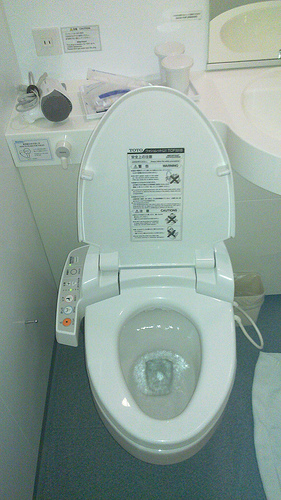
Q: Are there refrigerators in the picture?
A: No, there are no refrigerators.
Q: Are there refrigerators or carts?
A: No, there are no refrigerators or carts.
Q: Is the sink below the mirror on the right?
A: Yes, the sink is below the mirror.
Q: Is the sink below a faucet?
A: No, the sink is below the mirror.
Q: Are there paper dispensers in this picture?
A: No, there are no paper dispensers.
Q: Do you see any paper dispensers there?
A: No, there are no paper dispensers.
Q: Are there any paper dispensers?
A: No, there are no paper dispensers.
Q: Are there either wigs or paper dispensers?
A: No, there are no paper dispensers or wigs.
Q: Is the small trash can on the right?
A: Yes, the garbage can is on the right of the image.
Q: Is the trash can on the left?
A: No, the trash can is on the right of the image.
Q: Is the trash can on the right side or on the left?
A: The trash can is on the right of the image.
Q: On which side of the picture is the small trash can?
A: The trash bin is on the right of the image.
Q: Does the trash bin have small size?
A: Yes, the trash bin is small.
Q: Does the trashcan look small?
A: Yes, the trashcan is small.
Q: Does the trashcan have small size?
A: Yes, the trashcan is small.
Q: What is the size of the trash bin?
A: The trash bin is small.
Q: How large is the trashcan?
A: The trashcan is small.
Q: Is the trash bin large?
A: No, the trash bin is small.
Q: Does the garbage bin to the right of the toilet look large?
A: No, the trash can is small.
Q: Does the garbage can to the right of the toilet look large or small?
A: The trash can is small.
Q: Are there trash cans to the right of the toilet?
A: Yes, there is a trash can to the right of the toilet.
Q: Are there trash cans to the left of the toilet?
A: No, the trash can is to the right of the toilet.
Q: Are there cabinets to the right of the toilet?
A: No, there is a trash can to the right of the toilet.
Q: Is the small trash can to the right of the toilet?
A: Yes, the garbage bin is to the right of the toilet.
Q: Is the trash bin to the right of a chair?
A: No, the trash bin is to the right of the toilet.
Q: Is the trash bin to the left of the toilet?
A: No, the trash bin is to the right of the toilet.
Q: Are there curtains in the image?
A: No, there are no curtains.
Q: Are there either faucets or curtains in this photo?
A: No, there are no curtains or faucets.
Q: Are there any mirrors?
A: Yes, there is a mirror.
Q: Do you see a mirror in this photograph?
A: Yes, there is a mirror.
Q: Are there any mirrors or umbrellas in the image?
A: Yes, there is a mirror.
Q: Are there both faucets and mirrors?
A: No, there is a mirror but no faucets.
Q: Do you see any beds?
A: No, there are no beds.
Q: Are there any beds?
A: No, there are no beds.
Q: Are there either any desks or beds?
A: No, there are no beds or desks.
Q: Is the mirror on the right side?
A: Yes, the mirror is on the right of the image.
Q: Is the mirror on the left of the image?
A: No, the mirror is on the right of the image.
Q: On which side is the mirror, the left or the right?
A: The mirror is on the right of the image.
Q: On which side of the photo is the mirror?
A: The mirror is on the right of the image.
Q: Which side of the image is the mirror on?
A: The mirror is on the right of the image.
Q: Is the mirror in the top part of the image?
A: Yes, the mirror is in the top of the image.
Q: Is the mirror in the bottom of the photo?
A: No, the mirror is in the top of the image.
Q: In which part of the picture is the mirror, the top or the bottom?
A: The mirror is in the top of the image.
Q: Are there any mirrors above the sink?
A: Yes, there is a mirror above the sink.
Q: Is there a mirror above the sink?
A: Yes, there is a mirror above the sink.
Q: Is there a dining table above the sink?
A: No, there is a mirror above the sink.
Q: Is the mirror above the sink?
A: Yes, the mirror is above the sink.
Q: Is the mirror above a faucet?
A: No, the mirror is above the sink.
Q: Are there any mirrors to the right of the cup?
A: Yes, there is a mirror to the right of the cup.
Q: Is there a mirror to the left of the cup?
A: No, the mirror is to the right of the cup.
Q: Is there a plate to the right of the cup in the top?
A: No, there is a mirror to the right of the cup.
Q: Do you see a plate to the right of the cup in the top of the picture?
A: No, there is a mirror to the right of the cup.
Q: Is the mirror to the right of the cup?
A: Yes, the mirror is to the right of the cup.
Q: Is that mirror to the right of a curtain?
A: No, the mirror is to the right of the cup.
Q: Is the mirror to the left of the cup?
A: No, the mirror is to the right of the cup.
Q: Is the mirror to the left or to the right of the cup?
A: The mirror is to the right of the cup.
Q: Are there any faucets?
A: No, there are no faucets.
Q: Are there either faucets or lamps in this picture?
A: No, there are no faucets or lamps.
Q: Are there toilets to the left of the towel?
A: Yes, there is a toilet to the left of the towel.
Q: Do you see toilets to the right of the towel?
A: No, the toilet is to the left of the towel.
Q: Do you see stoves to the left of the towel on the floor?
A: No, there is a toilet to the left of the towel.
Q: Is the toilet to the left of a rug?
A: No, the toilet is to the left of the towel.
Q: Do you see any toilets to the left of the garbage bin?
A: Yes, there is a toilet to the left of the garbage bin.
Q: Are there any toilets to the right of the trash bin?
A: No, the toilet is to the left of the trash bin.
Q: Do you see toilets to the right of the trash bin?
A: No, the toilet is to the left of the trash bin.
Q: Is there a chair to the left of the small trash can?
A: No, there is a toilet to the left of the garbage bin.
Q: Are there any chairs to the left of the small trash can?
A: No, there is a toilet to the left of the garbage bin.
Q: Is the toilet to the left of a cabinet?
A: No, the toilet is to the left of the garbage bin.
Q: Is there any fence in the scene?
A: No, there are no fences.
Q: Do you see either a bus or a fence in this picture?
A: No, there are no fences or buses.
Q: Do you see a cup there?
A: Yes, there is a cup.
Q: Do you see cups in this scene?
A: Yes, there is a cup.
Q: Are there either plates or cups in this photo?
A: Yes, there is a cup.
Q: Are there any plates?
A: No, there are no plates.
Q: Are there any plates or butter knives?
A: No, there are no plates or butter knives.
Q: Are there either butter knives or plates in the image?
A: No, there are no plates or butter knives.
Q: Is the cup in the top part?
A: Yes, the cup is in the top of the image.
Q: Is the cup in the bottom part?
A: No, the cup is in the top of the image.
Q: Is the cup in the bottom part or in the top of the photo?
A: The cup is in the top of the image.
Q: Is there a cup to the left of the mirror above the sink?
A: Yes, there is a cup to the left of the mirror.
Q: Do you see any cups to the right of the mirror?
A: No, the cup is to the left of the mirror.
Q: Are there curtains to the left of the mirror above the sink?
A: No, there is a cup to the left of the mirror.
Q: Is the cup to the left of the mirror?
A: Yes, the cup is to the left of the mirror.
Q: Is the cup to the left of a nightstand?
A: No, the cup is to the left of the mirror.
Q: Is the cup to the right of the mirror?
A: No, the cup is to the left of the mirror.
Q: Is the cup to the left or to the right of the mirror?
A: The cup is to the left of the mirror.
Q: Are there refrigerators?
A: No, there are no refrigerators.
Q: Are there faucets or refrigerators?
A: No, there are no refrigerators or faucets.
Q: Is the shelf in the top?
A: Yes, the shelf is in the top of the image.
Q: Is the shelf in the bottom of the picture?
A: No, the shelf is in the top of the image.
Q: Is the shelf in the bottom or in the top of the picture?
A: The shelf is in the top of the image.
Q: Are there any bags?
A: No, there are no bags.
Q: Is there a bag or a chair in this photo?
A: No, there are no bags or chairs.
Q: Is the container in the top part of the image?
A: Yes, the container is in the top of the image.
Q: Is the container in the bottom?
A: No, the container is in the top of the image.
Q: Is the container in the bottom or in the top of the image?
A: The container is in the top of the image.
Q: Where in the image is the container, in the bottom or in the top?
A: The container is in the top of the image.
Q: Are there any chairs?
A: No, there are no chairs.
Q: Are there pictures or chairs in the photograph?
A: No, there are no chairs or pictures.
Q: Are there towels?
A: Yes, there is a towel.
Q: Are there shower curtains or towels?
A: Yes, there is a towel.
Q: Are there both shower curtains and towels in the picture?
A: No, there is a towel but no shower curtains.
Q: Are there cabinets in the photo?
A: No, there are no cabinets.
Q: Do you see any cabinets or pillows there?
A: No, there are no cabinets or pillows.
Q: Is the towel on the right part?
A: Yes, the towel is on the right of the image.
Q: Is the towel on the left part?
A: No, the towel is on the right of the image.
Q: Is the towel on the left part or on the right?
A: The towel is on the right of the image.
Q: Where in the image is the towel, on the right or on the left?
A: The towel is on the right of the image.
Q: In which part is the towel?
A: The towel is on the right of the image.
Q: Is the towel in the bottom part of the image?
A: Yes, the towel is in the bottom of the image.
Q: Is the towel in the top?
A: No, the towel is in the bottom of the image.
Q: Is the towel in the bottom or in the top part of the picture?
A: The towel is in the bottom of the image.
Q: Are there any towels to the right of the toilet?
A: Yes, there is a towel to the right of the toilet.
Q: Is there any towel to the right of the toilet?
A: Yes, there is a towel to the right of the toilet.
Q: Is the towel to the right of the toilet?
A: Yes, the towel is to the right of the toilet.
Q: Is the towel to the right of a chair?
A: No, the towel is to the right of the toilet.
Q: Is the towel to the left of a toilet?
A: No, the towel is to the right of a toilet.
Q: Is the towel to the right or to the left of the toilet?
A: The towel is to the right of the toilet.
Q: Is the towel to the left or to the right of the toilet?
A: The towel is to the right of the toilet.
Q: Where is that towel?
A: The towel is on the floor.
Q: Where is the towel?
A: The towel is on the floor.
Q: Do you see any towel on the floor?
A: Yes, there is a towel on the floor.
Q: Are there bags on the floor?
A: No, there is a towel on the floor.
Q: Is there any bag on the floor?
A: No, there is a towel on the floor.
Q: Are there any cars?
A: No, there are no cars.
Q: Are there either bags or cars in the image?
A: No, there are no cars or bags.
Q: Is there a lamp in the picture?
A: No, there are no lamps.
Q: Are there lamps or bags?
A: No, there are no lamps or bags.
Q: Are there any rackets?
A: No, there are no rackets.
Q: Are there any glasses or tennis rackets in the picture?
A: No, there are no tennis rackets or glasses.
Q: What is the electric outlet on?
A: The electric outlet is on the wall.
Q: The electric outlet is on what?
A: The electric outlet is on the wall.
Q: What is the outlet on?
A: The electric outlet is on the wall.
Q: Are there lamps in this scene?
A: No, there are no lamps.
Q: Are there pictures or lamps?
A: No, there are no lamps or pictures.